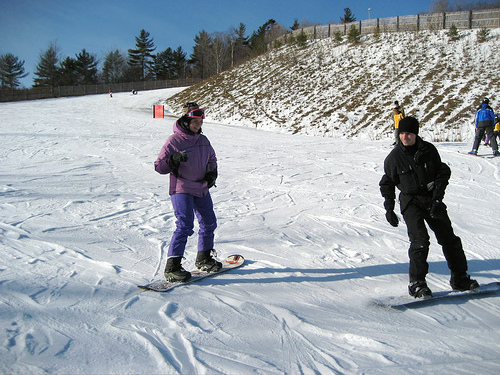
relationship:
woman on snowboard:
[170, 105, 226, 248] [141, 241, 252, 307]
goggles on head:
[184, 104, 220, 129] [184, 94, 227, 138]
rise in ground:
[144, 91, 178, 120] [66, 76, 245, 155]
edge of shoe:
[449, 269, 480, 293] [450, 261, 480, 296]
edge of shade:
[247, 253, 310, 280] [244, 255, 372, 290]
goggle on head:
[176, 106, 222, 123] [184, 94, 227, 138]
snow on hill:
[62, 145, 491, 371] [255, 43, 436, 134]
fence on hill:
[305, 8, 408, 36] [255, 43, 436, 134]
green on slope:
[256, 33, 341, 79] [270, 22, 434, 138]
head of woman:
[184, 94, 227, 138] [154, 102, 224, 284]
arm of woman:
[155, 138, 188, 173] [154, 102, 224, 284]